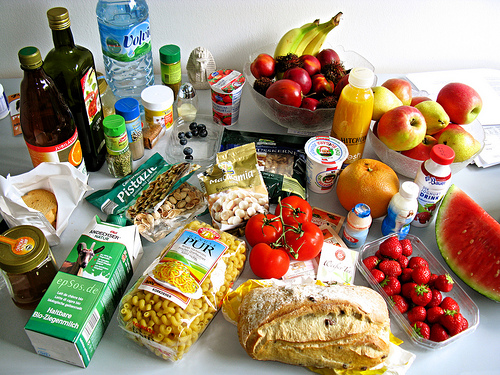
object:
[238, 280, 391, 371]
bread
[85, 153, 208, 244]
bag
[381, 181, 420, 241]
bin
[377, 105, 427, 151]
apples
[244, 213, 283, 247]
tomatoes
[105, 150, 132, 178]
spices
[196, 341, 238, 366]
table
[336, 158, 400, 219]
orange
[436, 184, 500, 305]
watermelon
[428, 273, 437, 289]
strawberry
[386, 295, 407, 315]
strawberry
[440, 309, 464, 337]
strawberry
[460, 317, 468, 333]
strawberry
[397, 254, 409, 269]
strawberry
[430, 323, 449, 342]
strawberry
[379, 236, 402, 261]
strawberry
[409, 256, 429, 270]
strawberry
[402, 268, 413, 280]
strawberry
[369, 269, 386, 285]
strawberry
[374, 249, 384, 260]
strawberry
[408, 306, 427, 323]
strawberry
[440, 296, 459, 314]
strawberry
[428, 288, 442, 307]
strawberry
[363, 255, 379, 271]
strawberry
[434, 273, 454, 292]
strawberry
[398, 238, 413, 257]
strawberry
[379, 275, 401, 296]
strawberry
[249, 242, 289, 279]
food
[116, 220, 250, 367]
bag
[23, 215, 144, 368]
milk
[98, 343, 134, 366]
table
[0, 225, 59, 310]
honey jar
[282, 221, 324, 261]
tomatoes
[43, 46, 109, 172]
olive oil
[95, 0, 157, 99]
water bottle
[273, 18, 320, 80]
banana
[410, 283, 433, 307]
strawberries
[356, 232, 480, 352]
carton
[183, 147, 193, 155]
blueberry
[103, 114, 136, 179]
glass jar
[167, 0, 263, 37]
white wall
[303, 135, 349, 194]
yogurt container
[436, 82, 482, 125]
apple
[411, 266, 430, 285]
strawberries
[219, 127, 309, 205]
pasta bag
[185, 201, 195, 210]
pistachio nuts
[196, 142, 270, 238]
bag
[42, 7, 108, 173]
bottles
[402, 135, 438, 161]
apples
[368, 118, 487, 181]
bowl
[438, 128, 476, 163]
apple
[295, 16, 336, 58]
bananas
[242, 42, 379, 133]
bowl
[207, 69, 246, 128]
yogurt container